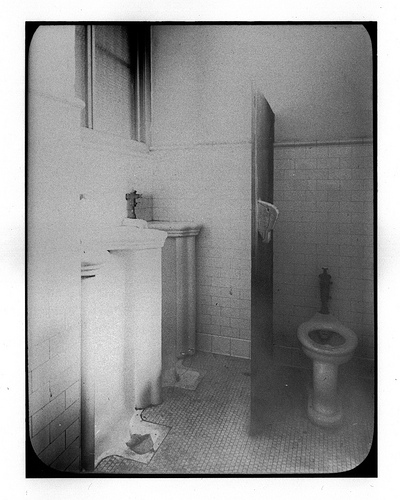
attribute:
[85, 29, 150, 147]
blinds — closed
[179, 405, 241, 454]
bathroom floor — tiled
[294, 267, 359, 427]
toilet — white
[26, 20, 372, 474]
wall — tiled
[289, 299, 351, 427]
toilet — white, dirty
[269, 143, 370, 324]
wall — tiled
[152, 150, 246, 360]
wall — tiled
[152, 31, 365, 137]
wall — tiled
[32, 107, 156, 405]
wall — tiled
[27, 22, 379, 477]
border — black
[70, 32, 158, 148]
window — closed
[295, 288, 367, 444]
toilet — white, tall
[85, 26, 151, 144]
window pane — dark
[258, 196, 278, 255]
dispenser — toilet paper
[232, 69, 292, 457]
divider — wooden, privacy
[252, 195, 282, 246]
dispenser — white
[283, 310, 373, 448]
toilet — white, porcelain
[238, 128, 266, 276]
divider — wall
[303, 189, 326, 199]
brick — white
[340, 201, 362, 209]
brick — white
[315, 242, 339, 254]
brick — white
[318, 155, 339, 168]
brick — white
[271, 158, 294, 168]
brick — white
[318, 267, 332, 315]
pipe — metal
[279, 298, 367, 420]
toilet — public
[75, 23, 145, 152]
window — dirty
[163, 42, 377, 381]
wall — tiled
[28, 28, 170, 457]
wall — tiled, white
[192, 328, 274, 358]
baseboard — tile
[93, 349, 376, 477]
floor — dirty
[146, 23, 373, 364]
wall — tiled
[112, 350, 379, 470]
tiles — dirty 